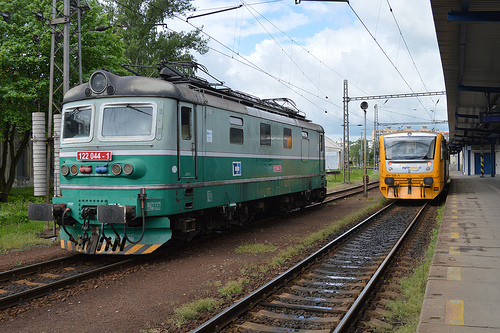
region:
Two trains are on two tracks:
[47, 5, 482, 301]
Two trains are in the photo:
[32, 70, 474, 320]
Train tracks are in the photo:
[61, 80, 468, 295]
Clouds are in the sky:
[165, 25, 460, 190]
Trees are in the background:
[11, 35, 296, 247]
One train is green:
[51, 46, 471, 291]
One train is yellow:
[345, 105, 460, 241]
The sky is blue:
[184, 20, 486, 202]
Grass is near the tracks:
[175, 245, 452, 330]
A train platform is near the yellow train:
[320, 61, 480, 329]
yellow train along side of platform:
[370, 125, 455, 209]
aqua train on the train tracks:
[42, 65, 330, 262]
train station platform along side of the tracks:
[419, 177, 498, 320]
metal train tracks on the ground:
[219, 210, 402, 332]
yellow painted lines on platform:
[437, 197, 467, 332]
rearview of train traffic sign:
[352, 96, 377, 198]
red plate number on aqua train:
[71, 145, 124, 164]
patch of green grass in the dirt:
[223, 237, 281, 259]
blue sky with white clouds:
[199, 10, 416, 74]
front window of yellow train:
[382, 132, 437, 164]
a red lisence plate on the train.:
[73, 144, 118, 166]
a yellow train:
[372, 120, 454, 205]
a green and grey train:
[37, 61, 337, 254]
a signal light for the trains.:
[356, 97, 379, 202]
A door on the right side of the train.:
[170, 90, 212, 193]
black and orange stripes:
[52, 222, 162, 262]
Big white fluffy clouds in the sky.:
[218, 15, 443, 133]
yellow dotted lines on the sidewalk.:
[444, 179, 469, 331]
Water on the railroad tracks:
[300, 218, 401, 328]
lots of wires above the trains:
[170, 2, 445, 144]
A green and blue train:
[47, 44, 342, 263]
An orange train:
[354, 97, 494, 222]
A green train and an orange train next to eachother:
[3, 20, 496, 260]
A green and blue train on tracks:
[32, 14, 345, 294]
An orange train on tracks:
[355, 107, 477, 244]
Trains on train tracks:
[2, 35, 482, 315]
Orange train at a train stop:
[310, 40, 493, 311]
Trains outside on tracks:
[35, 47, 467, 278]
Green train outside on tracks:
[2, 35, 354, 296]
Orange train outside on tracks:
[346, 82, 481, 312]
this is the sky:
[269, 10, 344, 43]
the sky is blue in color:
[294, 28, 308, 36]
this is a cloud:
[220, 11, 267, 28]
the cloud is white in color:
[218, 20, 238, 36]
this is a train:
[58, 81, 329, 214]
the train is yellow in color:
[393, 172, 423, 187]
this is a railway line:
[302, 267, 367, 318]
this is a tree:
[5, 5, 25, 204]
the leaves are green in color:
[5, 9, 35, 85]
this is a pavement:
[443, 210, 499, 326]